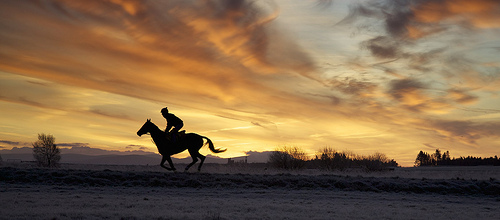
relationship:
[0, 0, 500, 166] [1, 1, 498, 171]
cloud in sky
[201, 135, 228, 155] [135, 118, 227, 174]
tail of horse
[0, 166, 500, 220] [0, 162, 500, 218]
dirt on ground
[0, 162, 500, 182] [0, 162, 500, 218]
dirt on ground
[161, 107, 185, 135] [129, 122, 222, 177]
man riding horse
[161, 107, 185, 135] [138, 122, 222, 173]
man riding horse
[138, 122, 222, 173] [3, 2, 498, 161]
horse against sunset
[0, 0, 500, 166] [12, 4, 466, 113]
cloud in sky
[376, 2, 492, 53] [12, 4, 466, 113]
cloud in sky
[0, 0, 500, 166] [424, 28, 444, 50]
cloud in sky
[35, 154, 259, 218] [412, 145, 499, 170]
field of trees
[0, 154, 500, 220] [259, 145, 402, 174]
field of trees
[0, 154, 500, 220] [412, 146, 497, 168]
field of trees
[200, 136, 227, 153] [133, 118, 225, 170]
tail of horse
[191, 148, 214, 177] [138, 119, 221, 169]
back legs of horse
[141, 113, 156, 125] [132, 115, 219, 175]
ears of horse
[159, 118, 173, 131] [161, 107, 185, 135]
arms of man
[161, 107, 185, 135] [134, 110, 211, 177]
man on horse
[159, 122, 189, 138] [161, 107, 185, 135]
legs on man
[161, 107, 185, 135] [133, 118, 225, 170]
man on horse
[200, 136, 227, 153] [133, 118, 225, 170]
tail on horse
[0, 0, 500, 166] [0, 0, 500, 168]
cloud in orange sky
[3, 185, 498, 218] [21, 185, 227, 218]
sand on ground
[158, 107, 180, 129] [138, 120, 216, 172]
man riding horse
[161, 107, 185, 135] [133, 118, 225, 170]
man riding horse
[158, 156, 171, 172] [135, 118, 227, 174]
leg of horse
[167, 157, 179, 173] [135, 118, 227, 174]
leg of horse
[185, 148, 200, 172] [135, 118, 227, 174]
leg of horse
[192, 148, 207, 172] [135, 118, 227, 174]
back legs of horse